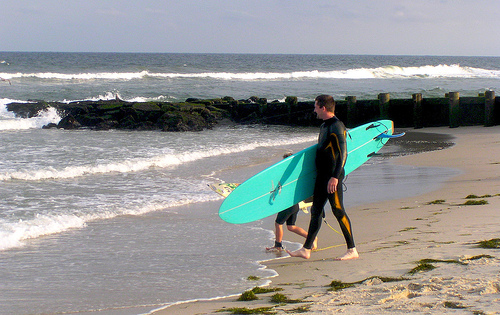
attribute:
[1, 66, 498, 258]
waves — splashing, white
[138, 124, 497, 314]
beach — wet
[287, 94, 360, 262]
man — barefoot, walking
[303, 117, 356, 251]
wet suit — black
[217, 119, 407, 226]
surfboard — turquoise, aqua, blue, green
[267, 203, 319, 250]
child — walking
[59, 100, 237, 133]
rocks — mossy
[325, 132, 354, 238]
design — yellow